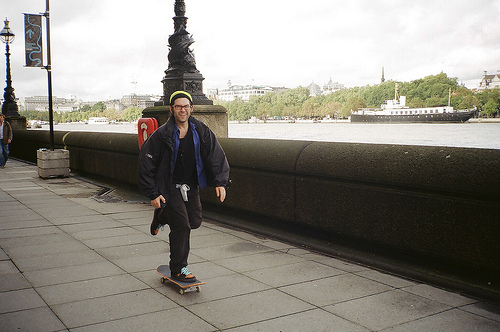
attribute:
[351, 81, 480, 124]
boat — large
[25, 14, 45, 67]
lines — squiggly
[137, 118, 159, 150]
object — red, orange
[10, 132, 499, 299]
wall — concrete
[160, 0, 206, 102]
statue — gray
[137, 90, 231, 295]
man — skateboarding, smiling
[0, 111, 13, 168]
person — walking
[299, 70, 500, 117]
trees — clustered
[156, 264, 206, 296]
skateboard — black, orange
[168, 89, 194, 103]
beanie — green, black, knit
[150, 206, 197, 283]
sneakers — orange, black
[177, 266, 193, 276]
laces — green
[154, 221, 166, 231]
laces — green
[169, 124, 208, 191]
shirt — blue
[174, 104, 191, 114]
glasses — black rimmed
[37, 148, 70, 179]
box — white, large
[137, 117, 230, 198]
jacket — dark blue